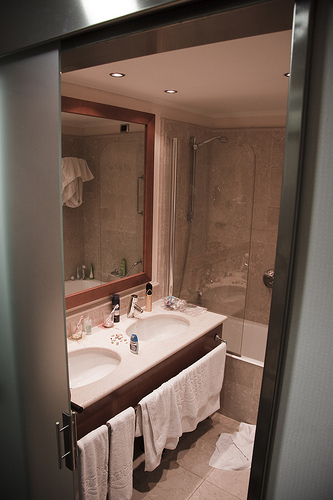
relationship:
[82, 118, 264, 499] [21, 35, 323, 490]
doorway of bathroom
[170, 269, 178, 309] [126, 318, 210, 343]
toothbrushes on sink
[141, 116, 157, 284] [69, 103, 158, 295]
frame on mirror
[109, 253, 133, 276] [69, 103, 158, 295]
body wash on mirror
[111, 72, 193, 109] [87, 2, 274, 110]
lights on ceiling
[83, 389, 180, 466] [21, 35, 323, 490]
towels in bathroom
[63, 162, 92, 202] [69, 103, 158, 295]
towel in mirror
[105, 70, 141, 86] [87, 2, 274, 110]
light in ceiling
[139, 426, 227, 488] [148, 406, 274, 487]
shadow on floor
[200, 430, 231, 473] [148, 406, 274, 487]
napkin on floor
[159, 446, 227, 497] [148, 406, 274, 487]
tiles on floor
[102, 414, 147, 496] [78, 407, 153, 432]
towel on rack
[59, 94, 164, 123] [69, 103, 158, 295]
edge on mirror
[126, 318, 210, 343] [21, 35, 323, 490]
sink in bathroom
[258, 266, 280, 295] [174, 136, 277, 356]
handle on shower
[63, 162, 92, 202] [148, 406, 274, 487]
towel on floor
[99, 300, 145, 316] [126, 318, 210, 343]
faucet on sink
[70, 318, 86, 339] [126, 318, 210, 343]
toothbrush holder on sink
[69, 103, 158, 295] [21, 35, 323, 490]
mirror in bathroom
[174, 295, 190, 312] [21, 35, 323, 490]
soap in bathroom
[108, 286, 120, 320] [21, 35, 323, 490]
shaving cream in bathroom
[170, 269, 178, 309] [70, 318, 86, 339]
toothbrushes in toothbrush holder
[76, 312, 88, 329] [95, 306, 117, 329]
toothbrushes in glass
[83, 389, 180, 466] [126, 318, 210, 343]
towels hanging from sink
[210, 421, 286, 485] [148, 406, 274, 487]
towel on floor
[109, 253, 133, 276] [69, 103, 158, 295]
bottle in mirror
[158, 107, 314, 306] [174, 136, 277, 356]
shield on shower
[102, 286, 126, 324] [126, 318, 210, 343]
canister on sink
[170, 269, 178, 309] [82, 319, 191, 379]
toothbrushes on counter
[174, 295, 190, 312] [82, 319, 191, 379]
soap on counter